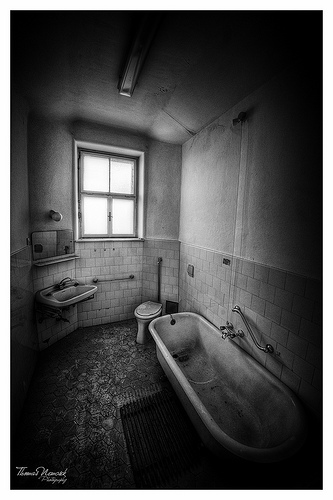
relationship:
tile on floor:
[63, 373, 84, 398] [39, 350, 111, 446]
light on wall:
[48, 206, 70, 227] [32, 119, 180, 337]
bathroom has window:
[10, 11, 322, 489] [78, 148, 135, 236]